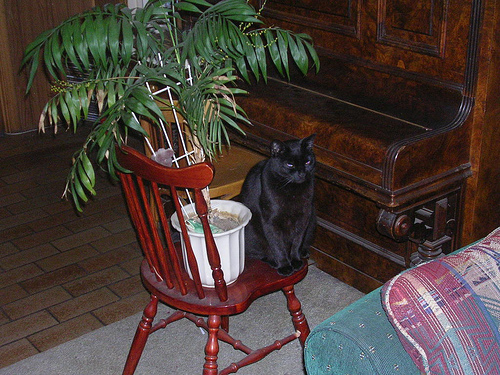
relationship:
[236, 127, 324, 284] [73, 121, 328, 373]
black cat on chair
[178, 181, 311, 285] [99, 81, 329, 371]
pot on chair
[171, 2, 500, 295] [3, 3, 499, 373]
brown piano in living room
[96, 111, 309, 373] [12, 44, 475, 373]
chair in living room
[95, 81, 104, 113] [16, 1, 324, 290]
leaf of plant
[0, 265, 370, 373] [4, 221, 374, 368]
carpet on floor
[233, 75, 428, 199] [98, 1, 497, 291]
cover of piano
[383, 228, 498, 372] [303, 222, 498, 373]
cushion on sofa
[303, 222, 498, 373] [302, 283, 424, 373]
sofa has arm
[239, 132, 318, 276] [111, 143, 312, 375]
black cat sitting on chair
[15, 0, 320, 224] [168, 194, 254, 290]
palm tree growing in pot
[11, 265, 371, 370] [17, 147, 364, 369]
carpet on ground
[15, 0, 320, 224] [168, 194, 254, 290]
palm tree in pot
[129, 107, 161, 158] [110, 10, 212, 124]
wire holding plant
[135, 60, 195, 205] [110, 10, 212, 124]
wire holding plant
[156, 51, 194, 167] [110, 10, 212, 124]
wire holding plant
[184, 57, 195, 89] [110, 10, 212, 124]
wire holding plant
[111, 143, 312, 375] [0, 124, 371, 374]
chair on floor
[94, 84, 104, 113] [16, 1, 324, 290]
leaf on plant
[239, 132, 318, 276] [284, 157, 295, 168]
black cat has eye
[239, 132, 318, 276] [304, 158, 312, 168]
black cat has eye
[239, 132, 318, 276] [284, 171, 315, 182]
black cat has whiskers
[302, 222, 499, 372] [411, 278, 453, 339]
couch has symbols